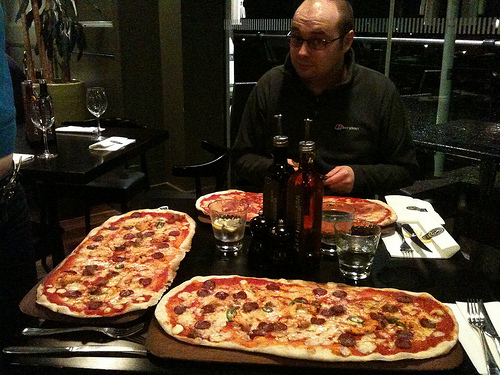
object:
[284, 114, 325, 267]
bottle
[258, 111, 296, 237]
bottle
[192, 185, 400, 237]
pizza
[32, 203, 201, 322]
pizza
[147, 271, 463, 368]
pizza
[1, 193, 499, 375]
table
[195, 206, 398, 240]
board